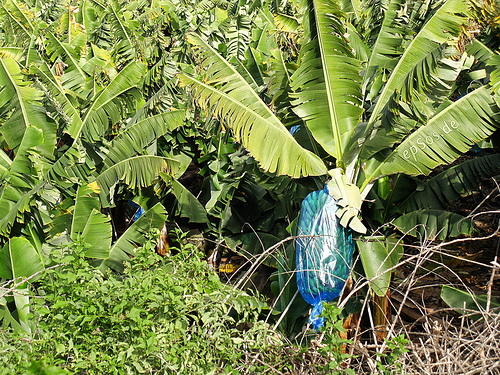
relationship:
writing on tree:
[317, 204, 340, 286] [175, 2, 497, 234]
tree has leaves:
[175, 2, 497, 234] [0, 238, 196, 327]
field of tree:
[50, 79, 475, 366] [175, 2, 497, 234]